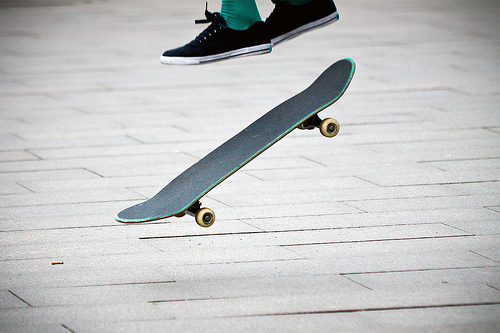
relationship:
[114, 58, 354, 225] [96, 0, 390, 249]
skateboard in air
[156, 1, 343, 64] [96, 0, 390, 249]
feet are in air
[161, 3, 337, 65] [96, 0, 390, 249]
shoes are in air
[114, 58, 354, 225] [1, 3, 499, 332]
skateboard above floor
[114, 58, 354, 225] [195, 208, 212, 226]
skateboard has wheel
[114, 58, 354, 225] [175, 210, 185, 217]
skateboard has wheel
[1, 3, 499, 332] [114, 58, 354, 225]
floor under skateboard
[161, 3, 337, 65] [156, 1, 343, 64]
shoes are on feet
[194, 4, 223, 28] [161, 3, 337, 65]
laces are on shoes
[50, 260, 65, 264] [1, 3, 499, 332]
butt on floor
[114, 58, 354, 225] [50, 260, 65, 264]
skateboard above butt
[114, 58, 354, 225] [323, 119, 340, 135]
skateboard has wheel